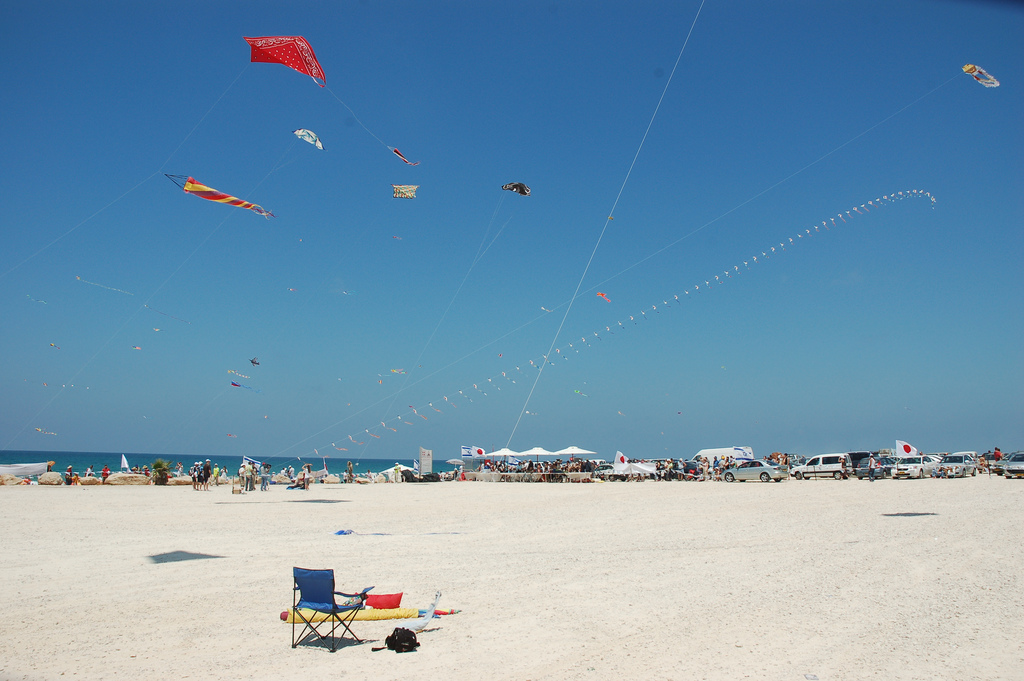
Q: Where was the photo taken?
A: At the beach.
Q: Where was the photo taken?
A: At the beach.